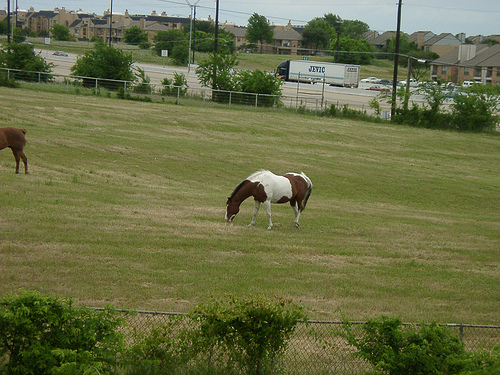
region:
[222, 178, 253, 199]
Horse has black mane.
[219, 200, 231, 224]
Horse has white on face.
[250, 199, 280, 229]
Horse's front legs are white.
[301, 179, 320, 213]
Horse has long tail.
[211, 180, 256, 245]
Horse is standing in grassy field.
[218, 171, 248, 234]
Horse is bending down to eat grass.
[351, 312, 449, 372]
Green bush in front of fence.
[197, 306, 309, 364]
Green bush in front of fence.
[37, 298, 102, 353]
Green bush in front of fence.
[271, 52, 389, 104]
Semi truck driving on road.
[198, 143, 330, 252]
a brown and white horse standing in a field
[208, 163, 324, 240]
a brown and white horse eating the grass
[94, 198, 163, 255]
green grass of the field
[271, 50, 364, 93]
a semi truck on the road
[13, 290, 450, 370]
several green plants growing on the fence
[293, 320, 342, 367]
grey chain link fence around the field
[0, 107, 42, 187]
the back end of a brown horse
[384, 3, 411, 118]
a wood telephone pole next to the road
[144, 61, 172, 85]
grey concrete surface of the road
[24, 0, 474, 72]
several buildings in the distance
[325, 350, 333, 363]
part of a fence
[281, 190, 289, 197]
part of an horse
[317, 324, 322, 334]
edge of a fence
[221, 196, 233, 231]
head of a horse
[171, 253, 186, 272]
par of a lawn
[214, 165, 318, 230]
horse grazing in field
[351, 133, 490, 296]
field of grass for grazing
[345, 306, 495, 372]
green plant life growing near fence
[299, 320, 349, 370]
metal fence enclosing area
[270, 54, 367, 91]
truck going down street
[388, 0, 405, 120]
pole that hangs utility lines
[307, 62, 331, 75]
lettering on the truck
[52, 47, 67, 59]
vehicle on the road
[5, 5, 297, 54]
rows of homes on street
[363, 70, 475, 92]
vehicles on a lot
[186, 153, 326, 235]
Horse standing in a field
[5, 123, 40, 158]
Horse standing in a field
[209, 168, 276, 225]
Horse standing in a field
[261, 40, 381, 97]
Truck driving down the road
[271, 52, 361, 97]
blue and white truck on the street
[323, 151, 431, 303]
green field of grass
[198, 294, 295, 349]
bushes growing on the fence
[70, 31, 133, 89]
bushes on the ground